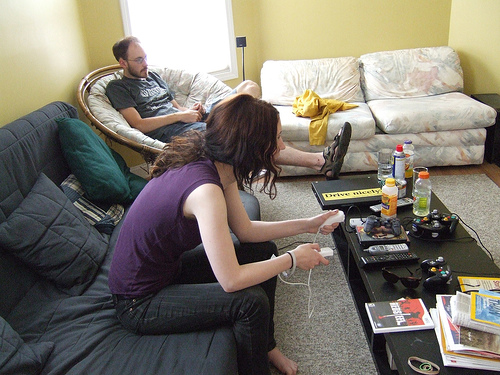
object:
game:
[364, 297, 435, 334]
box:
[364, 298, 434, 335]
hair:
[146, 92, 282, 200]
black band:
[287, 252, 293, 269]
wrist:
[283, 250, 297, 270]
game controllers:
[411, 208, 458, 241]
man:
[107, 36, 353, 178]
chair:
[78, 65, 234, 164]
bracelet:
[286, 250, 296, 278]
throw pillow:
[0, 172, 110, 296]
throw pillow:
[53, 118, 149, 202]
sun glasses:
[382, 266, 427, 289]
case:
[311, 176, 382, 210]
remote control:
[358, 252, 420, 268]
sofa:
[260, 45, 497, 176]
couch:
[0, 100, 263, 373]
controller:
[420, 256, 453, 290]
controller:
[317, 210, 345, 231]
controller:
[313, 247, 334, 258]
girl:
[109, 93, 338, 375]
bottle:
[380, 178, 399, 220]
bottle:
[411, 171, 431, 218]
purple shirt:
[109, 157, 224, 297]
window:
[121, 0, 241, 82]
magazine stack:
[429, 288, 500, 372]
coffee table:
[332, 170, 499, 373]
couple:
[111, 35, 352, 375]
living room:
[1, 10, 500, 375]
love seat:
[260, 44, 497, 176]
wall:
[79, 0, 142, 165]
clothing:
[292, 88, 360, 146]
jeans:
[114, 232, 277, 375]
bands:
[407, 356, 440, 374]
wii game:
[364, 297, 434, 335]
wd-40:
[390, 144, 405, 180]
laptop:
[310, 176, 382, 210]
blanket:
[292, 88, 358, 145]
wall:
[0, 0, 107, 149]